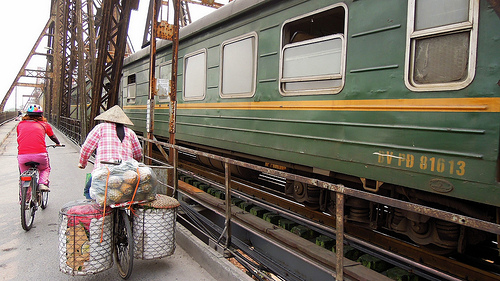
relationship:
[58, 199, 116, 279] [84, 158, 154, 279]
basket on side of bicycle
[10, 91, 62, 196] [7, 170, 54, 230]
woman on bike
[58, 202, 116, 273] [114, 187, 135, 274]
basket on bike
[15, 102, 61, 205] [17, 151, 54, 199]
woman wearing pants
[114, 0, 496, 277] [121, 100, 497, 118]
passenger train with stripe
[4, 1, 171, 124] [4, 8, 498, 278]
bridge in scene